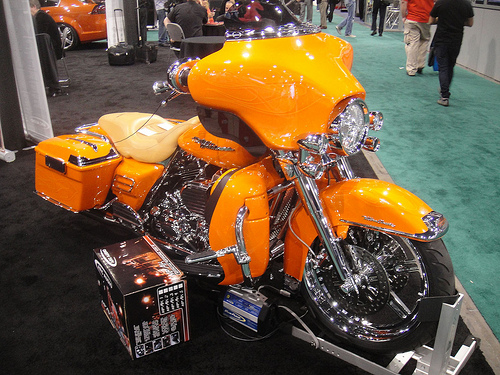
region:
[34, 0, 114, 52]
orange vehicle in background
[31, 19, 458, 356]
a yellow parked motorcycle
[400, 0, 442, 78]
person in orange shirt and beige pants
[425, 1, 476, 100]
person all in black walking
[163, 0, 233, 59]
people sitting at a table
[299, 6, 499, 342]
a green carpeted walkway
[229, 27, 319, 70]
lights reflecting onto top of motorcycle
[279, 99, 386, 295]
silver trimming on front of motorcycle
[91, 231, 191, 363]
a box on floor beside bike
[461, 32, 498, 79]
shadows from people on wall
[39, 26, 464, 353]
bike at a show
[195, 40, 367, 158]
bike is very orange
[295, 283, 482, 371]
bike is on stands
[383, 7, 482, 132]
people are on carpet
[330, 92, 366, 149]
bike has a light in front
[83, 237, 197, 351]
box is near the bike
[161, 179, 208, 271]
bike has chrome throughout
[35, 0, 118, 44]
car in the background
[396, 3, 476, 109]
people walking on the carpet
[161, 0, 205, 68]
people are sitting in chair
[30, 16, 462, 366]
one beautiful motorcycle on display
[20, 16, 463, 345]
one pretty motorcycle on display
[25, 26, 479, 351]
one nice motorcycle on display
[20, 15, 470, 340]
one great motorcycle on display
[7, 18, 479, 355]
one awesome motorcycle on display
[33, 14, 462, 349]
one polished motorcycle on display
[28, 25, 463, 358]
beautifully polished motorcycle on display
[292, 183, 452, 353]
front wheel of motorbike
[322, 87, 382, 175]
front headlight of motorcycle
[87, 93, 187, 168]
orange seat of a motorcycle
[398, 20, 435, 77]
tan cotton cargo pants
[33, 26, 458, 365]
yellow and orange motorcycle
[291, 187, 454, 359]
black motorcycle wheel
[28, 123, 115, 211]
yellow toolbox on back of yellow and black motorcycle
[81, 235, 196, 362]
box on floor next to yellow and black motorcycle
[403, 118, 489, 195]
green carpet with tread marks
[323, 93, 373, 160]
silver headlight on front of motorcycle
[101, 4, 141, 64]
black roller suitcase with long handle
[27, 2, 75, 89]
person sitting down in chair on black carpet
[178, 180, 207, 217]
silver grill on side of motorcycle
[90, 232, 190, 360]
a box sitting next to the motorcycle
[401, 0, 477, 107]
people walking by the motorcycles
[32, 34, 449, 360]
a fancy yellow motorcycle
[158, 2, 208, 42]
a person sitting at a table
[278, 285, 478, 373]
a device to keep the motorcycle in place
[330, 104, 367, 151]
the headlight of the motorcycle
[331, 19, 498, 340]
the turquoise rug that people are walking on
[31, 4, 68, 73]
another person sitting at a table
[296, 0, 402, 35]
more people walking around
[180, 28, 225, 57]
a table covered with a black tablecloth